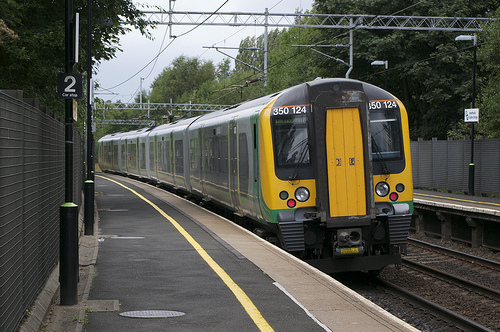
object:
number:
[273, 106, 307, 116]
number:
[369, 101, 398, 109]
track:
[378, 237, 499, 332]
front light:
[287, 199, 296, 208]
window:
[274, 115, 311, 167]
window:
[370, 121, 401, 152]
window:
[239, 133, 249, 178]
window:
[190, 138, 197, 169]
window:
[205, 135, 229, 174]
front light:
[396, 183, 405, 192]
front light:
[375, 181, 390, 197]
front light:
[279, 191, 289, 201]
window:
[175, 139, 183, 176]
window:
[128, 143, 136, 168]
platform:
[85, 171, 421, 332]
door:
[325, 108, 367, 217]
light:
[456, 35, 476, 43]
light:
[371, 61, 386, 67]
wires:
[104, 38, 176, 92]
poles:
[145, 10, 494, 33]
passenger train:
[97, 77, 414, 273]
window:
[158, 140, 171, 172]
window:
[114, 145, 119, 165]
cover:
[118, 309, 188, 319]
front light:
[295, 186, 310, 202]